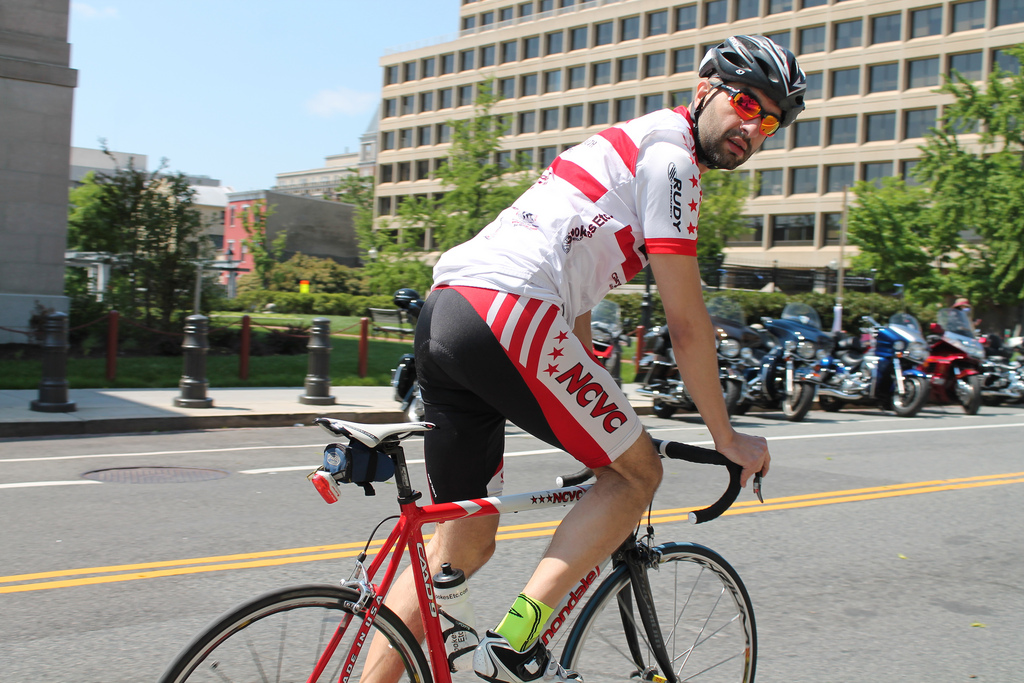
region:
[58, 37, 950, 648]
this is a city center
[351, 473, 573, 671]
the bike frame is red and white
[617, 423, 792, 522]
the handle bars are black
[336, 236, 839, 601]
the shorts are red and white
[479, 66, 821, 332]
the jersey is red and white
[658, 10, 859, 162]
the helmet is black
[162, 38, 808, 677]
A cyclist on the move.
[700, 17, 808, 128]
A dark safety helmet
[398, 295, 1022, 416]
The bikes parked on the roadside.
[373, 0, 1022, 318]
The high storied building.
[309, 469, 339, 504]
A rear red safety light.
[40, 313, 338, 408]
The dark road barriers.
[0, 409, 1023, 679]
The yellow line marked freeway.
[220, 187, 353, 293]
The red painted building in the background.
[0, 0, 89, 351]
The partially blocked building on the left.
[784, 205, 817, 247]
window on the building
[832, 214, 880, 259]
window on the building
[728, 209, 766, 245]
window on the building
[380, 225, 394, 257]
window on the building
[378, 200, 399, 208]
window on the building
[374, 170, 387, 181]
window on the building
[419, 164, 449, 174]
window on the building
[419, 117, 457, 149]
window on the building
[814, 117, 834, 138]
window on the building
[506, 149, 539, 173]
window on the building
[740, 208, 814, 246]
window on the building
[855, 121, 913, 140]
window on the building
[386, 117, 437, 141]
window on the building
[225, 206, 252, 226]
window on the building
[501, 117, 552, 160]
window on the building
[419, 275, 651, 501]
black, red, and white shorts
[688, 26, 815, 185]
head is turned to the side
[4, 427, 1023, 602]
parallel yellow lines on the ground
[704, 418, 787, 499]
hand is on the handlebar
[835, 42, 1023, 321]
dark green leaves on the tree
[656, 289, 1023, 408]
a row of parked bikes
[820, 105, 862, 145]
window on the side of the building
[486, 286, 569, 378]
red and white stripes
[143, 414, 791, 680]
red, white, and black bike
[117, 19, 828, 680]
a man rides a bike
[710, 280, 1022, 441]
motorcycles parked on the road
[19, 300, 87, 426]
a black pole on the street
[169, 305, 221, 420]
a black pole on the street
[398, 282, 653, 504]
the short is black, red and white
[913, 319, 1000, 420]
the motorcycle is red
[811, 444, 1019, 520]
two yellow lines on the road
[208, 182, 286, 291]
the building is red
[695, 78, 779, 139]
red lenses in sunglass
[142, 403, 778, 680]
red racing bicycle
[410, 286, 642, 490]
red, wite and black biking shorts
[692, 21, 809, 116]
black and white bicycle helmet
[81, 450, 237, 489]
manhole cover on the road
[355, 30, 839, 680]
man riding large bicycle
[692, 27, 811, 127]
man wearing safety helmet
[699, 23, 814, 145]
mans helmet is black and white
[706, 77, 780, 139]
mans glasses are red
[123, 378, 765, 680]
mans bicycle is red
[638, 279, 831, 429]
motorcyle parked by sidewalk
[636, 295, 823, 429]
first motorcycle is blue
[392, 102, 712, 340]
mans shirt is red and white